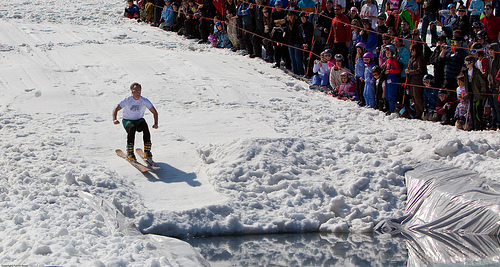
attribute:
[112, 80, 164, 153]
man — skiing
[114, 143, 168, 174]
skis — yellow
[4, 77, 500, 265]
snow — white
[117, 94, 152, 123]
shirt — white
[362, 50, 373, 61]
helmet — purple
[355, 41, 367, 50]
helmet — purple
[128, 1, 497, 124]
crowd — of people, standing, watching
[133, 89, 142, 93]
sunglasses — shiny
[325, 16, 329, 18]
rope — red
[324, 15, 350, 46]
shirt — read, red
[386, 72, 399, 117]
pants — blue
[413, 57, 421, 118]
clothes — brown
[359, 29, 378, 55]
jacket — blue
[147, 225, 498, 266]
hole — deep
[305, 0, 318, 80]
lines — orange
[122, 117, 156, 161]
ski pants — green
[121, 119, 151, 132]
shorts — green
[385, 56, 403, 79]
shirt — red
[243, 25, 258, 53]
pants — black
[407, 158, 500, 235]
tarp — white